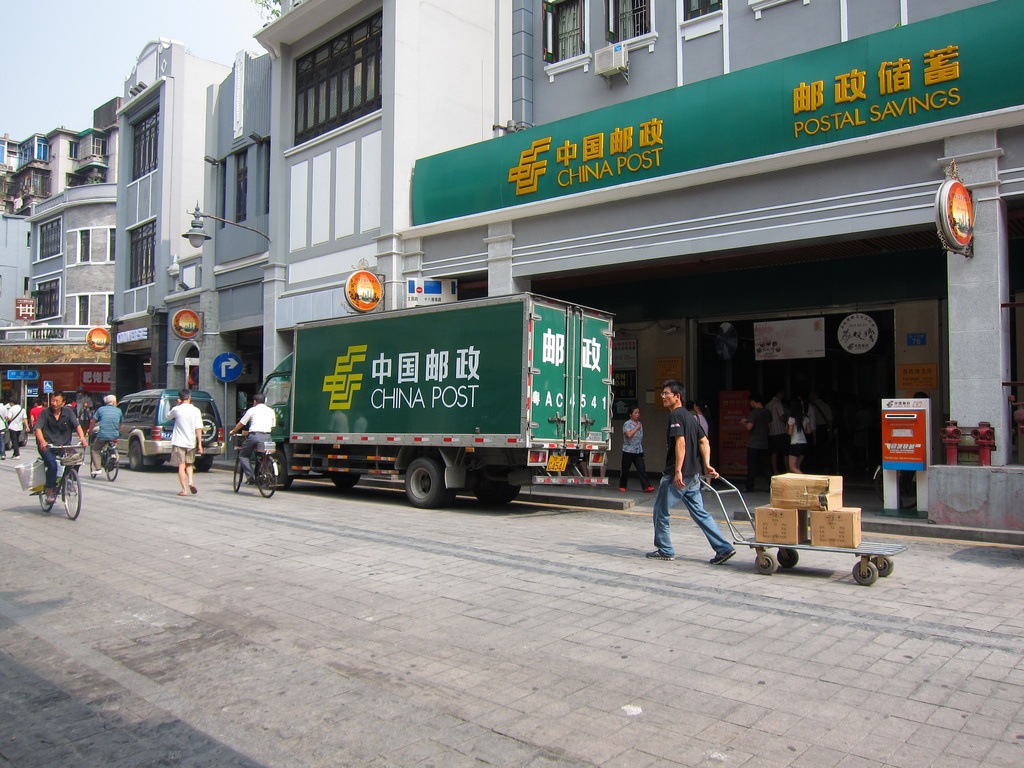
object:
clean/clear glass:
[308, 87, 316, 129]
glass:
[130, 218, 157, 289]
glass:
[698, 310, 896, 394]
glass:
[693, 320, 756, 398]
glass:
[764, 359, 847, 476]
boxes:
[755, 473, 862, 549]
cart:
[694, 472, 910, 587]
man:
[646, 380, 736, 565]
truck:
[237, 291, 618, 509]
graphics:
[322, 344, 481, 410]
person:
[166, 389, 203, 496]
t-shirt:
[167, 403, 204, 449]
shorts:
[170, 445, 197, 464]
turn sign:
[213, 351, 244, 382]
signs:
[86, 182, 976, 353]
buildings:
[0, 0, 1024, 532]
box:
[882, 398, 931, 471]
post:
[883, 470, 928, 512]